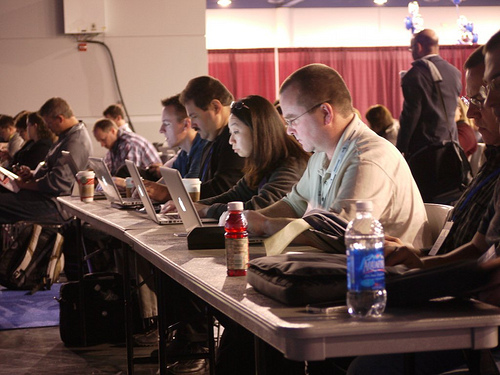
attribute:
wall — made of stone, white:
[2, 0, 205, 162]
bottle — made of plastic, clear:
[343, 198, 387, 319]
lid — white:
[76, 169, 96, 181]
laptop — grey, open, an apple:
[156, 162, 263, 245]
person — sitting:
[218, 62, 432, 250]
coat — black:
[395, 51, 475, 177]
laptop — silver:
[122, 158, 219, 224]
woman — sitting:
[189, 94, 308, 227]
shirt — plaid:
[104, 127, 163, 176]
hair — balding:
[277, 62, 356, 119]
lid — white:
[353, 198, 374, 213]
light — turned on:
[369, 0, 393, 8]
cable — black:
[79, 37, 136, 134]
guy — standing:
[394, 26, 473, 202]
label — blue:
[348, 245, 386, 294]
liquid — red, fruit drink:
[225, 211, 251, 277]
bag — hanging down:
[412, 57, 473, 199]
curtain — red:
[208, 45, 483, 127]